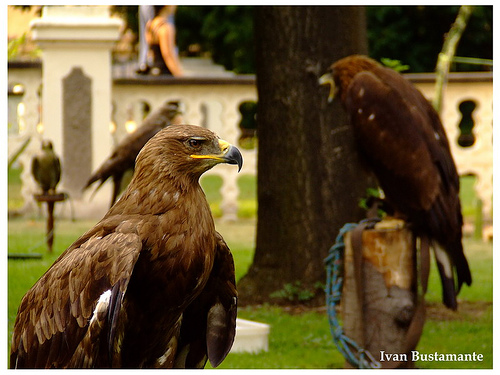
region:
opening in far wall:
[449, 85, 479, 153]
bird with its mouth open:
[315, 54, 341, 108]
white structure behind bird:
[220, 306, 275, 360]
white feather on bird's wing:
[86, 283, 112, 335]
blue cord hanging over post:
[325, 216, 382, 364]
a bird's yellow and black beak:
[201, 132, 246, 175]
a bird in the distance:
[26, 133, 68, 252]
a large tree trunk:
[246, 3, 365, 299]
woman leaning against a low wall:
[133, 3, 191, 101]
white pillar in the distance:
[31, 5, 115, 220]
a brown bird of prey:
[315, 56, 477, 311]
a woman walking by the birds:
[141, 5, 193, 80]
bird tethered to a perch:
[315, 51, 474, 367]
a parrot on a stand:
[28, 132, 70, 250]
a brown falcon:
[11, 122, 250, 368]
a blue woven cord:
[323, 220, 389, 365]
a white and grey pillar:
[28, 6, 119, 221]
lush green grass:
[12, 216, 492, 373]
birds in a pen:
[12, 47, 477, 363]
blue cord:
[314, 218, 379, 351]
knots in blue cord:
[321, 241, 352, 286]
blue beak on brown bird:
[220, 144, 247, 177]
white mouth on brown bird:
[311, 70, 346, 102]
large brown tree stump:
[333, 212, 455, 352]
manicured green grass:
[9, 231, 40, 272]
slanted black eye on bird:
[173, 133, 212, 152]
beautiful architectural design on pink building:
[452, 89, 483, 157]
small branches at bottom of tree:
[270, 274, 335, 309]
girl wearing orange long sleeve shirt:
[138, 4, 192, 87]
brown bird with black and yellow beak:
[4, 111, 267, 373]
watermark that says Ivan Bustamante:
[373, 342, 488, 366]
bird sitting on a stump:
[308, 62, 460, 338]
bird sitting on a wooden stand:
[25, 136, 68, 249]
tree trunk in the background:
[249, 42, 418, 286]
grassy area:
[255, 302, 341, 369]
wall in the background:
[17, 62, 486, 200]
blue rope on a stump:
[311, 194, 399, 369]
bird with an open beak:
[300, 49, 396, 109]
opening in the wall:
[443, 97, 488, 165]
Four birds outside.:
[16, 68, 486, 360]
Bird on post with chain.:
[319, 54, 471, 372]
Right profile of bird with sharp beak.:
[148, 125, 249, 191]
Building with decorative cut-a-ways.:
[12, 45, 494, 212]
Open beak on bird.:
[317, 69, 346, 111]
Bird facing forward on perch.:
[34, 130, 66, 255]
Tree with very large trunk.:
[219, 12, 374, 359]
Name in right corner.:
[379, 341, 499, 369]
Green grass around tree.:
[235, 243, 490, 368]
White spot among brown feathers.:
[75, 248, 211, 363]